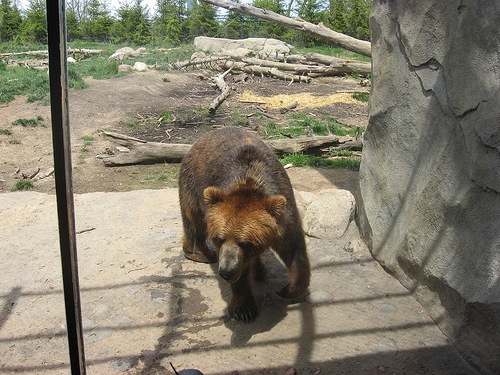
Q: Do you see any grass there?
A: Yes, there is grass.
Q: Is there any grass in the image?
A: Yes, there is grass.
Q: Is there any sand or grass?
A: Yes, there is grass.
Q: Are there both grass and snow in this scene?
A: No, there is grass but no snow.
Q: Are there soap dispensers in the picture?
A: No, there are no soap dispensers.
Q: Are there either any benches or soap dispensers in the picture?
A: No, there are no soap dispensers or benches.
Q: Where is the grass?
A: The grass is on the ground.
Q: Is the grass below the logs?
A: Yes, the grass is below the logs.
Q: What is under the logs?
A: The grass is under the logs.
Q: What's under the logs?
A: The grass is under the logs.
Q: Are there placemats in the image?
A: No, there are no placemats.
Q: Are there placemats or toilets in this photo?
A: No, there are no placemats or toilets.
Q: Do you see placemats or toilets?
A: No, there are no placemats or toilets.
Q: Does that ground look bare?
A: Yes, the ground is bare.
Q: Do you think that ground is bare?
A: Yes, the ground is bare.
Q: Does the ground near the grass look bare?
A: Yes, the ground is bare.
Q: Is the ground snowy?
A: No, the ground is bare.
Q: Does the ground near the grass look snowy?
A: No, the ground is bare.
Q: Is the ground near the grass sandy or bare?
A: The ground is bare.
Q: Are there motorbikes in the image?
A: No, there are no motorbikes.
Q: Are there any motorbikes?
A: No, there are no motorbikes.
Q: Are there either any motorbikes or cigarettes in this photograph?
A: No, there are no motorbikes or cigarettes.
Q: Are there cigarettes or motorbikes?
A: No, there are no motorbikes or cigarettes.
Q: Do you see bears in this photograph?
A: Yes, there is a bear.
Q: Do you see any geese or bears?
A: Yes, there is a bear.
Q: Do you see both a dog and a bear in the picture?
A: No, there is a bear but no dogs.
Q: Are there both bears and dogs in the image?
A: No, there is a bear but no dogs.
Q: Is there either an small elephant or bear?
A: Yes, there is a small bear.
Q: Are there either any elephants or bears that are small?
A: Yes, the bear is small.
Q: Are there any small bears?
A: Yes, there is a small bear.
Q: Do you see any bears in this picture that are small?
A: Yes, there is a bear that is small.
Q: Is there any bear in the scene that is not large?
A: Yes, there is a small bear.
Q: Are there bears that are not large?
A: Yes, there is a small bear.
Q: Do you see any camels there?
A: No, there are no camels.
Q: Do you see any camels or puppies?
A: No, there are no camels or puppies.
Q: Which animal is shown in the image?
A: The animal is a bear.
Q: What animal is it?
A: The animal is a bear.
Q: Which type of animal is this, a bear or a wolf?
A: This is a bear.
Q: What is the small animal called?
A: The animal is a bear.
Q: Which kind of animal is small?
A: The animal is a bear.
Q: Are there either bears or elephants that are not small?
A: No, there is a bear but it is small.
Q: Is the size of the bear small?
A: Yes, the bear is small.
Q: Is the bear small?
A: Yes, the bear is small.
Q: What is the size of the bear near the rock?
A: The bear is small.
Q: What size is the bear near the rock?
A: The bear is small.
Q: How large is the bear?
A: The bear is small.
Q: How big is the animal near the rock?
A: The bear is small.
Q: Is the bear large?
A: No, the bear is small.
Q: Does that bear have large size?
A: No, the bear is small.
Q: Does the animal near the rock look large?
A: No, the bear is small.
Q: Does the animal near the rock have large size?
A: No, the bear is small.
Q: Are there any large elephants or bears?
A: No, there is a bear but it is small.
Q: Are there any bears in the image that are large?
A: No, there is a bear but it is small.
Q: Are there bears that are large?
A: No, there is a bear but it is small.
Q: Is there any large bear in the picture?
A: No, there is a bear but it is small.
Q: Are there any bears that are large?
A: No, there is a bear but it is small.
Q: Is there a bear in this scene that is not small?
A: No, there is a bear but it is small.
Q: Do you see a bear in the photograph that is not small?
A: No, there is a bear but it is small.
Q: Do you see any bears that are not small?
A: No, there is a bear but it is small.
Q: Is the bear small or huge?
A: The bear is small.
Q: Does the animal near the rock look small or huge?
A: The bear is small.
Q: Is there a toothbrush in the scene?
A: No, there are no toothbrushes.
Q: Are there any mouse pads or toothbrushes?
A: No, there are no toothbrushes or mouse pads.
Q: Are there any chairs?
A: No, there are no chairs.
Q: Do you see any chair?
A: No, there are no chairs.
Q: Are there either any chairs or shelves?
A: No, there are no chairs or shelves.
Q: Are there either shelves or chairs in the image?
A: No, there are no chairs or shelves.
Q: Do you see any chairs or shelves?
A: No, there are no chairs or shelves.